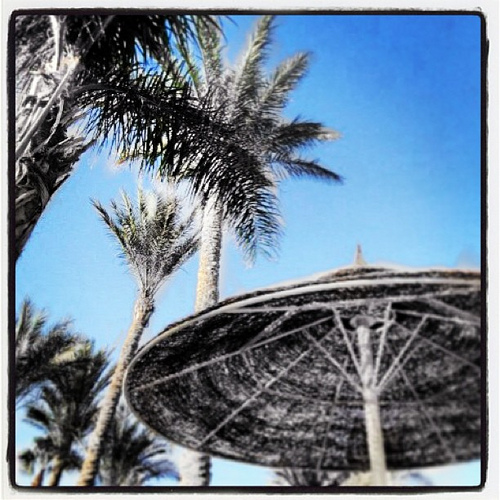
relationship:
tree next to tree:
[0, 0, 343, 309] [8, 16, 283, 263]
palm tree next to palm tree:
[16, 298, 76, 404] [28, 335, 114, 496]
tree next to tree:
[145, 28, 345, 308] [0, 0, 343, 309]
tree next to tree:
[0, 0, 343, 309] [0, 0, 343, 309]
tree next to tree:
[0, 0, 343, 309] [11, 314, 123, 494]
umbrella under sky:
[126, 264, 488, 465] [13, 13, 484, 485]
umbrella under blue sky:
[119, 242, 482, 487] [20, 13, 479, 265]